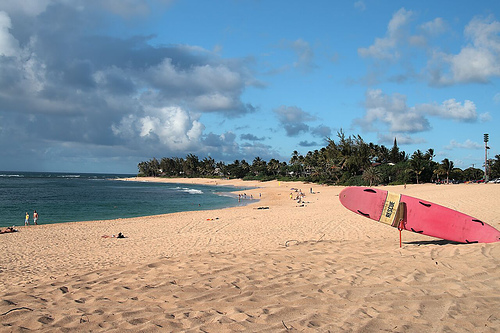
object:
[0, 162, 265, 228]
ocean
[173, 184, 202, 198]
waves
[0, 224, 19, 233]
person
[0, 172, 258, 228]
water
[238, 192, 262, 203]
people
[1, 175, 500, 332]
sand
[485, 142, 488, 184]
metal post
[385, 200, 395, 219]
writing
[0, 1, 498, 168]
clouds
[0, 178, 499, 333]
beach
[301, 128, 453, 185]
trees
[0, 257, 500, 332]
foot prints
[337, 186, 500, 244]
board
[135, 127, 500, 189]
leaves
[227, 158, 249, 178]
tree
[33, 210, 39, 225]
people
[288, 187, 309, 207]
people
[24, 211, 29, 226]
people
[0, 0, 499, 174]
sky